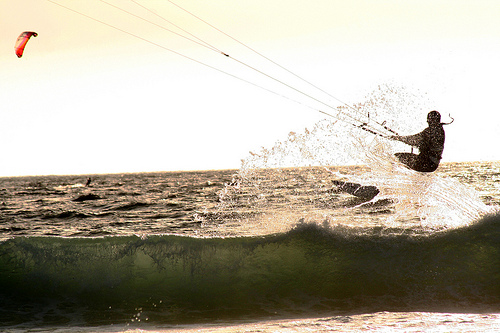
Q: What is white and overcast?
A: The sky.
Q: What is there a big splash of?
A: Water.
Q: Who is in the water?
A: A person.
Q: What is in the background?
A: Water.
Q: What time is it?
A: Afternoon.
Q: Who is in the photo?
A: A person.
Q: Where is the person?
A: In the ocean.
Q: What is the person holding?
A: A device.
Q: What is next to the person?
A: Water.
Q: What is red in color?
A: The thing in the sky.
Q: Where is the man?
A: The ocean.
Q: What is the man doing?
A: Windsurfing.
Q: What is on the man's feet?
A: A surfboard.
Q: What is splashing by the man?
A: The water.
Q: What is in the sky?
A: A kite.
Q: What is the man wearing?
A: A wetsuit.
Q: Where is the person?
A: On a surfboard.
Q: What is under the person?
A: A surfboard.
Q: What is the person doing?
A: Surfing.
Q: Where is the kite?
A: In the sky.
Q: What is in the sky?
A: The kite.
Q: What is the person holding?
A: A handle.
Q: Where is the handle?
A: In the person's hands.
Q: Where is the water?
A: Under the surfboard.